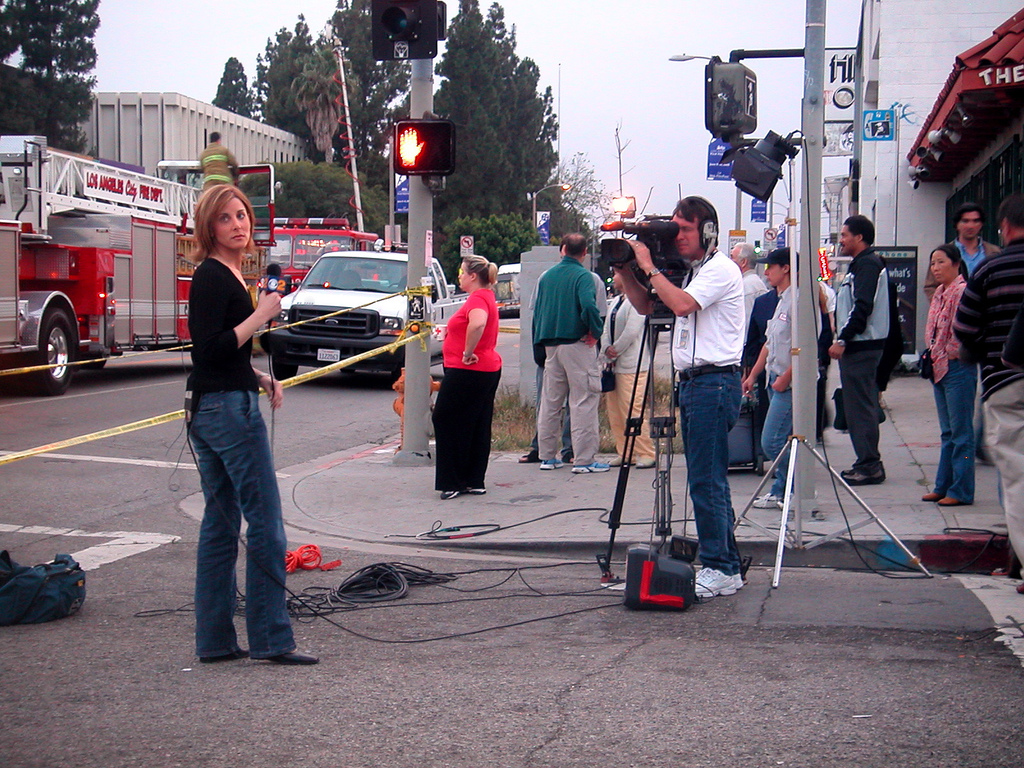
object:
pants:
[184, 389, 296, 658]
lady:
[187, 184, 322, 667]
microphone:
[257, 263, 287, 334]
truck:
[265, 250, 471, 381]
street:
[0, 301, 1024, 768]